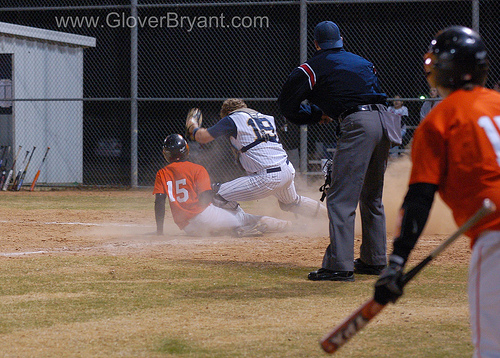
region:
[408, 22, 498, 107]
Batter wearing a black helmet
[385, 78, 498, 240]
Player wearing a orange jersey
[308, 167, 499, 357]
player holding a metal bat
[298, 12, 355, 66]
umpire wearing a black hat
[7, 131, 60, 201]
Bats leaning against a fence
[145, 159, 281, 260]
player sliding into home plate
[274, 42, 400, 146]
umpire wearing a blue jersey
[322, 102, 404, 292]
umpire wearing grey pants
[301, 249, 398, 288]
umpire wearing black shoes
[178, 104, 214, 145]
Player wearing a catchers glove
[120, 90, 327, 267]
catcher making play on runner at home plate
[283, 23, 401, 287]
umpire prepares to make call at home plate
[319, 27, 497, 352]
batter in on deck circle watching runner slide into home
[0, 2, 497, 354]
baseball game in progress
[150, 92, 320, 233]
catcher tries to make play at home plate on sliding runner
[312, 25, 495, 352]
baseball player in orange shirt white pants and blue batting helmet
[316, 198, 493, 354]
TPX aluminum baseball bat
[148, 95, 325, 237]
baseball catcher blocking home plate against runner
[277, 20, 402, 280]
baseball umpire in grey pants, blue shirt, black shoes and blue cap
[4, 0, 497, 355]
home plate area of baseball diamond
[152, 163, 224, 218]
the shirt is orange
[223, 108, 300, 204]
the clothes are white and black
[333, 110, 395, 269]
the pants are grey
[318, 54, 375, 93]
the shirt is blue in color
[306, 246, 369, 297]
the shoes are black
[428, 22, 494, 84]
the helmet is black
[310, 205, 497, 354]
the bat is wooden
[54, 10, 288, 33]
the website is gloverbryant.com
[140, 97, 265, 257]
the man is on the ground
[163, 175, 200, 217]
number 15 is on the shirt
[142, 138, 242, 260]
A baseball ball player on the ground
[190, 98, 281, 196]
A baseball ball player on the ground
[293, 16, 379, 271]
A baseball ball coach on the field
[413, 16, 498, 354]
A baseball ball player on the field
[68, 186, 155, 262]
A dusty baseball field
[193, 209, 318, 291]
A dusty baseball field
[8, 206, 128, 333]
A dusty baseball field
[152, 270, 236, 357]
A dusty baseball field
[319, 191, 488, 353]
A wooden baseball racket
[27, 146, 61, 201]
A wooden baseball racket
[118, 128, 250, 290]
man playing baseball on field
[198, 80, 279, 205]
man playing baseball on field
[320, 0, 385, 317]
man playing baseball on field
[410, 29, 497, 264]
man playing baseball on field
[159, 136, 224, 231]
orange shirt on baseball player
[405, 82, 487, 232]
orange shirt on baseball player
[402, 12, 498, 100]
black helmet on batter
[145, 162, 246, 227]
white number 15 on shirt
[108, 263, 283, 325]
short grass on baseball field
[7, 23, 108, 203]
white building on left